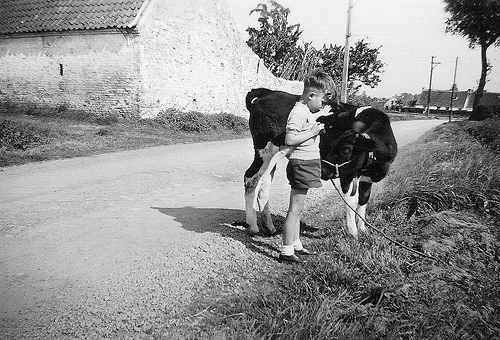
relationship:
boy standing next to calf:
[278, 70, 336, 263] [244, 88, 398, 240]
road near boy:
[2, 117, 449, 338] [278, 70, 336, 263]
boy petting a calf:
[277, 68, 335, 265] [244, 88, 398, 240]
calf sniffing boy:
[244, 88, 398, 240] [278, 70, 336, 263]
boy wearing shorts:
[277, 68, 335, 265] [286, 154, 325, 189]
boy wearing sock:
[278, 70, 336, 263] [278, 244, 293, 254]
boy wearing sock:
[278, 70, 336, 263] [295, 239, 304, 249]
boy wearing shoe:
[278, 70, 336, 263] [276, 253, 303, 264]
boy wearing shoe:
[278, 70, 336, 263] [296, 249, 315, 255]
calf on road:
[244, 88, 398, 240] [2, 117, 449, 338]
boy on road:
[278, 70, 336, 263] [2, 117, 449, 338]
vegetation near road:
[294, 121, 499, 339] [2, 117, 449, 338]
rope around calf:
[328, 159, 442, 279] [244, 88, 398, 240]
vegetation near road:
[244, 113, 497, 339] [2, 117, 449, 338]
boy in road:
[278, 70, 336, 263] [86, 179, 132, 267]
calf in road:
[244, 88, 398, 240] [86, 179, 132, 267]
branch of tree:
[467, 37, 492, 117] [441, 0, 484, 118]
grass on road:
[226, 120, 500, 335] [2, 117, 449, 338]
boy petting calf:
[278, 70, 336, 263] [244, 88, 398, 240]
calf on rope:
[244, 88, 398, 240] [330, 179, 445, 265]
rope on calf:
[330, 179, 445, 265] [244, 88, 398, 240]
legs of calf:
[235, 158, 277, 257] [244, 88, 398, 240]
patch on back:
[347, 101, 380, 117] [266, 89, 370, 124]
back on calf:
[266, 89, 370, 124] [244, 88, 398, 240]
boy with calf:
[278, 70, 336, 263] [244, 88, 398, 240]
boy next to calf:
[278, 70, 336, 263] [244, 88, 398, 240]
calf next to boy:
[238, 83, 402, 250] [273, 64, 341, 269]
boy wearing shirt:
[278, 70, 336, 263] [284, 100, 323, 160]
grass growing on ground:
[222, 128, 499, 335] [2, 105, 484, 335]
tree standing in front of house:
[246, 0, 305, 77] [1, 1, 307, 123]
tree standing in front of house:
[274, 42, 323, 82] [1, 1, 307, 123]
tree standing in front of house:
[315, 40, 386, 111] [1, 1, 307, 123]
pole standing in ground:
[340, 1, 356, 102] [2, 105, 484, 335]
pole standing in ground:
[426, 55, 437, 111] [2, 105, 484, 335]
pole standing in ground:
[448, 54, 461, 112] [2, 105, 484, 335]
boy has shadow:
[278, 70, 336, 263] [154, 201, 332, 270]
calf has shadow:
[244, 88, 398, 240] [154, 201, 332, 270]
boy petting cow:
[278, 70, 336, 263] [220, 73, 406, 245]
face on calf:
[319, 103, 373, 193] [244, 88, 398, 240]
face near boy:
[319, 103, 373, 193] [270, 65, 357, 288]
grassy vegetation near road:
[255, 116, 497, 338] [2, 117, 449, 338]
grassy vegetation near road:
[2, 94, 250, 166] [2, 117, 449, 338]